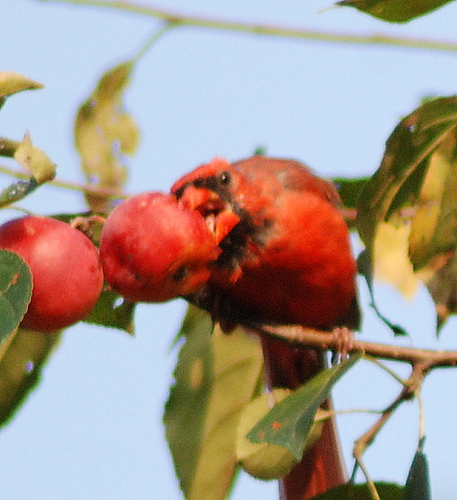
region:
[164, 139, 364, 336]
The bird is red.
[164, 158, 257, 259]
The bird has a red beak.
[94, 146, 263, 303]
The bird is eating a fruit.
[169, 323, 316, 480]
The leaves are green.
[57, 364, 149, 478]
The sky is blue.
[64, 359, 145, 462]
The sky is clear.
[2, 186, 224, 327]
Two fruits are in the picture.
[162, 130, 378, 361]
The bird is sitting on a branch.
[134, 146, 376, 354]
The bird is black and red.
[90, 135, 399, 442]
The bird is sitting in a tree.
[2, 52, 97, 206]
green leaves on the tree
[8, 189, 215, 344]
red fruit hangs from the branches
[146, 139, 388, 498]
red bird eating fruit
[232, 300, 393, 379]
bird grips the tree branch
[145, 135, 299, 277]
bird has black marking on its face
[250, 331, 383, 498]
bird has long tail feathers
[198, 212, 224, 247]
bird's pink tongue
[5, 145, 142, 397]
holes in the leaves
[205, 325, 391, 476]
leaf is torn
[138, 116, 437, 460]
the bird's mouth is open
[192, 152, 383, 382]
A bird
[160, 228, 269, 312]
A bird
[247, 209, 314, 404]
A bird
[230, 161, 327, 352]
A bird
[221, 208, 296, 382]
A bird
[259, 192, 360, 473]
A bird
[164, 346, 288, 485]
The leaves are visible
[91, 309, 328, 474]
The leaves are visible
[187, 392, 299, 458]
The leaves are visible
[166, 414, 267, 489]
The leaves are visible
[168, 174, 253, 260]
bird eating a berry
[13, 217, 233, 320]
two red berries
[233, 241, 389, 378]
bird is a robin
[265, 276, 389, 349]
bird sitting on a branch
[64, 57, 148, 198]
leaf has holes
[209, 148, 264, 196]
bird's eye is black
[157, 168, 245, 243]
bird's beak is red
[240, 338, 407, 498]
bird's tail is red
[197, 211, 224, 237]
bird's tongue is pink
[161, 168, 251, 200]
black around the bird's beak